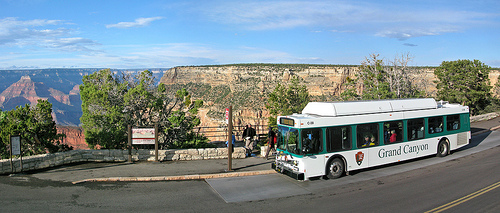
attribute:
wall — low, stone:
[1, 110, 484, 174]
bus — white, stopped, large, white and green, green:
[269, 94, 474, 182]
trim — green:
[272, 110, 471, 158]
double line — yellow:
[419, 180, 485, 209]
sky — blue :
[0, 0, 499, 71]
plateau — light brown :
[155, 63, 498, 142]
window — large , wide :
[325, 124, 354, 154]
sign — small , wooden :
[6, 130, 26, 176]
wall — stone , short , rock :
[0, 145, 243, 175]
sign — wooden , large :
[127, 121, 160, 162]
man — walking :
[264, 125, 277, 156]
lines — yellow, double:
[442, 175, 487, 203]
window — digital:
[264, 109, 302, 135]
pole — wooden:
[214, 105, 259, 183]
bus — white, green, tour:
[249, 86, 487, 174]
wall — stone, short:
[70, 126, 194, 197]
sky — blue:
[17, 19, 77, 64]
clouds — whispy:
[33, 8, 133, 62]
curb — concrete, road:
[94, 170, 266, 189]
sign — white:
[6, 134, 35, 171]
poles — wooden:
[0, 152, 30, 189]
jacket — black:
[239, 125, 255, 144]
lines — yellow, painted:
[437, 183, 479, 211]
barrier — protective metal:
[177, 110, 256, 165]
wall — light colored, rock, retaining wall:
[64, 149, 157, 171]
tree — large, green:
[437, 55, 466, 105]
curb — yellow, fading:
[107, 165, 218, 186]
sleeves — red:
[265, 120, 284, 161]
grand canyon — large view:
[380, 142, 433, 161]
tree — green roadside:
[74, 76, 144, 152]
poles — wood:
[126, 123, 161, 163]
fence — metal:
[156, 128, 265, 143]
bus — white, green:
[270, 91, 469, 178]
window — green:
[300, 128, 322, 154]